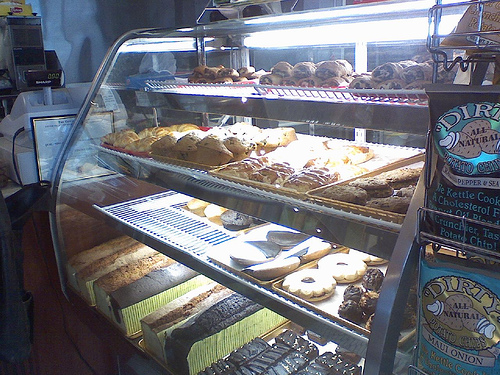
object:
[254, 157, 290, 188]
doughnuts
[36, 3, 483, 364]
case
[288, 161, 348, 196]
doughnut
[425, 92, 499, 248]
bag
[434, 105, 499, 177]
natural potatos chip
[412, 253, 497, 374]
chips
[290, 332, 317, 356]
brownies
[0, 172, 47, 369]
stand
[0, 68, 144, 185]
cash register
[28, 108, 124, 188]
paper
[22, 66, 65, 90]
screen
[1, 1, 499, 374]
picture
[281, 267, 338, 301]
cookies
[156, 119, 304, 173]
tray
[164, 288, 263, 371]
bread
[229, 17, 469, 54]
light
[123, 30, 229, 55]
light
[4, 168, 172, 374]
floor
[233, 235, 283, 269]
donuts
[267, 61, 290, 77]
croisant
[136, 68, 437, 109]
shelf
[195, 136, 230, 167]
muffin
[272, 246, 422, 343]
tray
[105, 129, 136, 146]
croissant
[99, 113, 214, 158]
tray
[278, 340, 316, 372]
icing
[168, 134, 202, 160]
muffins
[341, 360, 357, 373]
nuts